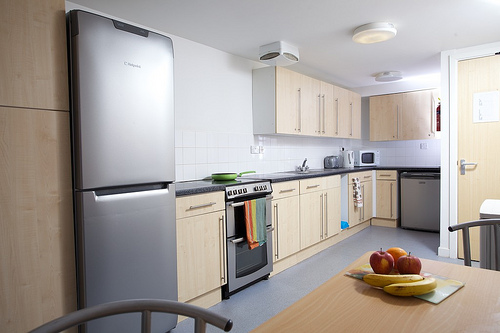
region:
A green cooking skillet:
[208, 170, 255, 180]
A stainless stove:
[224, 177, 272, 291]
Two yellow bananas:
[361, 272, 437, 296]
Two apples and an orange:
[369, 245, 421, 274]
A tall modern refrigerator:
[70, 8, 178, 330]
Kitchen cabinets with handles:
[253, 69, 437, 140]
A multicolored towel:
[243, 195, 265, 246]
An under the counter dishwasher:
[398, 165, 439, 232]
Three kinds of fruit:
[356, 245, 440, 300]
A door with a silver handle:
[453, 53, 498, 260]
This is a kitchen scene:
[2, 2, 498, 332]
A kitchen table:
[240, 244, 498, 331]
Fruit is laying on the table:
[350, 245, 442, 299]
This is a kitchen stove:
[211, 170, 277, 297]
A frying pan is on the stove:
[209, 167, 257, 182]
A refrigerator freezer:
[64, 5, 179, 331]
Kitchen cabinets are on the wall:
[246, 62, 436, 142]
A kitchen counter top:
[171, 160, 376, 195]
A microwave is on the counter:
[355, 145, 382, 168]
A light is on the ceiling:
[351, 18, 399, 47]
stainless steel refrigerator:
[72, 8, 177, 325]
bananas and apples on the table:
[352, 244, 435, 296]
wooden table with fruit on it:
[242, 248, 499, 331]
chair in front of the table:
[24, 303, 233, 330]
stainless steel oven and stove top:
[205, 169, 274, 291]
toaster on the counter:
[323, 153, 344, 170]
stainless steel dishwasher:
[396, 168, 442, 231]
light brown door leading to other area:
[453, 60, 498, 264]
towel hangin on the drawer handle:
[353, 182, 363, 210]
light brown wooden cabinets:
[273, 63, 359, 138]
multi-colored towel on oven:
[241, 197, 269, 251]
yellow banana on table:
[380, 275, 439, 297]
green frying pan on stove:
[208, 168, 257, 180]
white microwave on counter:
[350, 148, 381, 168]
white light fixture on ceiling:
[351, 22, 398, 47]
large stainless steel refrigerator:
[73, 14, 175, 331]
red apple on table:
[368, 245, 395, 277]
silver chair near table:
[25, 298, 236, 331]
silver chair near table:
[439, 215, 499, 273]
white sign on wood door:
[471, 89, 499, 123]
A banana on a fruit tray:
[386, 282, 432, 297]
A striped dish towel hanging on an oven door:
[249, 203, 266, 244]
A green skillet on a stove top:
[213, 170, 256, 176]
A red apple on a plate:
[371, 253, 394, 270]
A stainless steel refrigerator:
[83, 51, 171, 184]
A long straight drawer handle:
[186, 199, 221, 209]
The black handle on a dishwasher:
[404, 173, 443, 178]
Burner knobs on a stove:
[228, 190, 247, 196]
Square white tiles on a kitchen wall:
[191, 151, 208, 167]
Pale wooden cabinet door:
[6, 118, 70, 174]